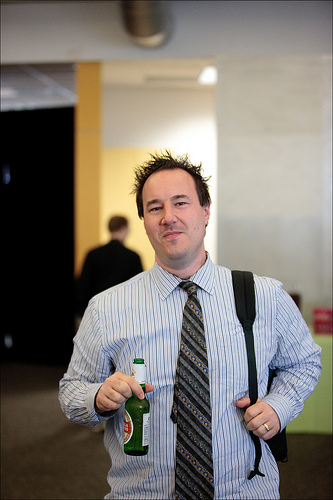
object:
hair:
[129, 148, 212, 220]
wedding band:
[263, 424, 270, 431]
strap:
[232, 270, 265, 481]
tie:
[170, 280, 215, 500]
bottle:
[123, 358, 150, 456]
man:
[57, 151, 322, 499]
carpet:
[3, 365, 332, 500]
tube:
[121, 2, 174, 52]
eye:
[150, 207, 163, 213]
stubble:
[161, 248, 188, 261]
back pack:
[231, 270, 288, 479]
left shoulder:
[211, 260, 284, 326]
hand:
[235, 396, 280, 441]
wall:
[2, 2, 332, 273]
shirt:
[58, 250, 321, 499]